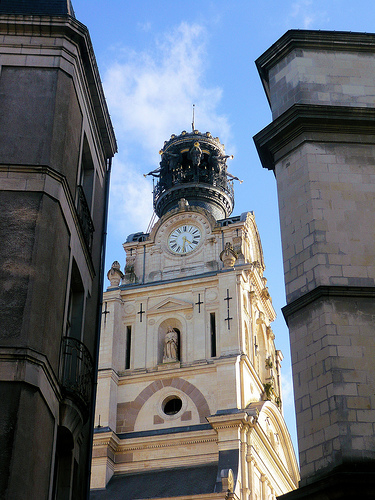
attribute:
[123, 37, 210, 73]
sky — blue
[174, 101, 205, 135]
pole — metal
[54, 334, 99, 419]
rail — wrought iron